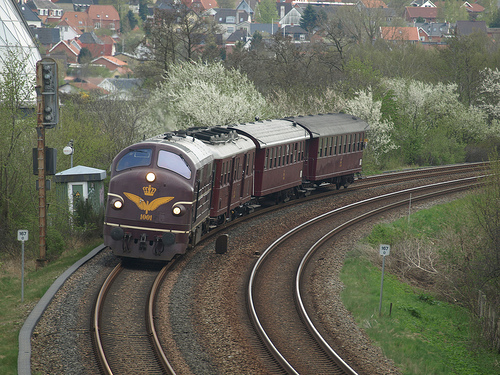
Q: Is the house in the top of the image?
A: Yes, the house is in the top of the image.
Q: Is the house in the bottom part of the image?
A: No, the house is in the top of the image.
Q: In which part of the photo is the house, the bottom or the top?
A: The house is in the top of the image.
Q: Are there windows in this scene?
A: Yes, there is a window.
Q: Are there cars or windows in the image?
A: Yes, there is a window.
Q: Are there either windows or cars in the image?
A: Yes, there is a window.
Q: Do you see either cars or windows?
A: Yes, there is a window.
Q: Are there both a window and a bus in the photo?
A: No, there is a window but no buses.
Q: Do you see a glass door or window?
A: Yes, there is a glass window.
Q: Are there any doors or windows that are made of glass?
A: Yes, the window is made of glass.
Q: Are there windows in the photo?
A: Yes, there is a window.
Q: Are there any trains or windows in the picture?
A: Yes, there is a window.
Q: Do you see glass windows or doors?
A: Yes, there is a glass window.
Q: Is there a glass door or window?
A: Yes, there is a glass window.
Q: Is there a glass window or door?
A: Yes, there is a glass window.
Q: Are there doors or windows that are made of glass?
A: Yes, the window is made of glass.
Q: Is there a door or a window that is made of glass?
A: Yes, the window is made of glass.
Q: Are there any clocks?
A: No, there are no clocks.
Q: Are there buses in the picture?
A: No, there are no buses.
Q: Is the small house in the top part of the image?
A: Yes, the house is in the top of the image.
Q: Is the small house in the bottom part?
A: No, the house is in the top of the image.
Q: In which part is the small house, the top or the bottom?
A: The house is in the top of the image.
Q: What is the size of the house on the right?
A: The house is small.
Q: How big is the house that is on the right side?
A: The house is small.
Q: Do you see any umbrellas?
A: No, there are no umbrellas.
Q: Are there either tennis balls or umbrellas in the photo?
A: No, there are no umbrellas or tennis balls.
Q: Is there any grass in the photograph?
A: Yes, there is grass.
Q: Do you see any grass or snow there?
A: Yes, there is grass.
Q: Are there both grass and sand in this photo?
A: No, there is grass but no sand.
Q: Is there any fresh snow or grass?
A: Yes, there is fresh grass.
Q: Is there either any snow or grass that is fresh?
A: Yes, the grass is fresh.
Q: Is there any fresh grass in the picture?
A: Yes, there is fresh grass.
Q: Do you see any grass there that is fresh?
A: Yes, there is grass that is fresh.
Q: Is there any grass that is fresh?
A: Yes, there is grass that is fresh.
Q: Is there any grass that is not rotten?
A: Yes, there is fresh grass.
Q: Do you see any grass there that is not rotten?
A: Yes, there is fresh grass.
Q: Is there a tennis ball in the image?
A: No, there are no tennis balls.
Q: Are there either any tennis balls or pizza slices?
A: No, there are no tennis balls or pizza slices.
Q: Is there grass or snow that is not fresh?
A: No, there is grass but it is fresh.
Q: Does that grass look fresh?
A: Yes, the grass is fresh.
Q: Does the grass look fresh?
A: Yes, the grass is fresh.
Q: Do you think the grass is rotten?
A: No, the grass is fresh.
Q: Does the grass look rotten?
A: No, the grass is fresh.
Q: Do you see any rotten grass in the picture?
A: No, there is grass but it is fresh.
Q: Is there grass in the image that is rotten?
A: No, there is grass but it is fresh.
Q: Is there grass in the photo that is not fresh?
A: No, there is grass but it is fresh.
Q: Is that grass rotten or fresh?
A: The grass is fresh.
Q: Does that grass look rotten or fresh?
A: The grass is fresh.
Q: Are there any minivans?
A: No, there are no minivans.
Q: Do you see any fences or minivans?
A: No, there are no minivans or fences.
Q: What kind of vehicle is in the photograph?
A: The vehicle is a train car.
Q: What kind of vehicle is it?
A: The vehicle is a train car.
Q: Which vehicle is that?
A: This is a train car.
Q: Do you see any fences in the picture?
A: No, there are no fences.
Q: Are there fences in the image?
A: No, there are no fences.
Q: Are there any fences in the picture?
A: No, there are no fences.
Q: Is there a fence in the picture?
A: No, there are no fences.